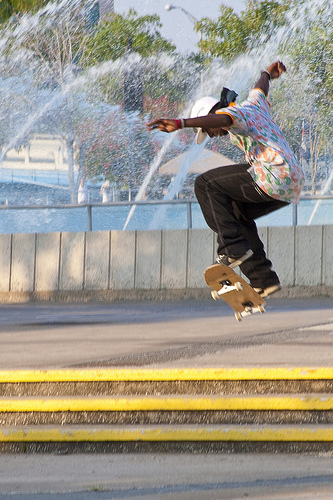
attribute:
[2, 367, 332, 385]
line — yellow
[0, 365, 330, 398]
step — yellow, painted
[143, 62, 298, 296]
person — skating, airborne, jumping, flying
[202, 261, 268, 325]
skateboard — brown, small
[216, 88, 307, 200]
shirt — multicolored, mulicolored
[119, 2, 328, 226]
spout — jumping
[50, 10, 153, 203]
tree — large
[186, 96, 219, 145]
cap — white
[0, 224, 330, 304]
wall — cement, wooden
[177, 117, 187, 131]
band — red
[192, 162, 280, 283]
pants — black, jeans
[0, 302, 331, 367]
sidewalk — grey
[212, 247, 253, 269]
shoe — black